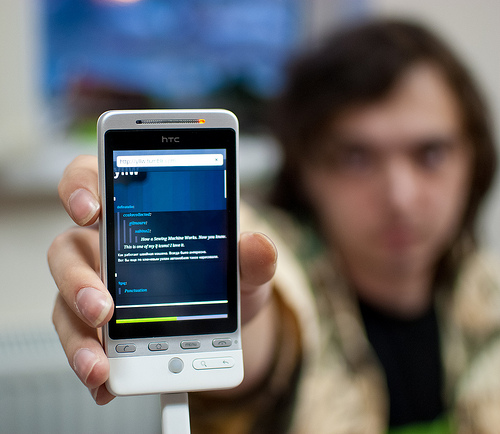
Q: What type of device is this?
A: Cell Phone.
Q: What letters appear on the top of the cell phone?
A: Htc.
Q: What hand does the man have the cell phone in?
A: Right.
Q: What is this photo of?
A: A man.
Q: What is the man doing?
A: Holding a phone.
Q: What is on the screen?
A: A program.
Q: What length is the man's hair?
A: Long.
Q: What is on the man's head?
A: His hair.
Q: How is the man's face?
A: Blurry.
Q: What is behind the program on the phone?
A: A blue screen.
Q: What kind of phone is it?
A: A htc.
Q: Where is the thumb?
A: On the phone.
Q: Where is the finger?
A: On the phone.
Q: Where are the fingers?
A: On the phone.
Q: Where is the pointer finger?
A: On the phone.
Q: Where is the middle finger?
A: On the phone.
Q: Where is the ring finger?
A: On the phone.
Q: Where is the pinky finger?
A: On the phone.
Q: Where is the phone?
A: In the hand.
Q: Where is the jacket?
A: On the man.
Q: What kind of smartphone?
A: HTC.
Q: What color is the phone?
A: White.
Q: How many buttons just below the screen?
A: Four.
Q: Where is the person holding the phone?
A: In their hand.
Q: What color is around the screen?
A: Black.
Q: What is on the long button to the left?
A: Magnifying glass.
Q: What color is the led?
A: Amber.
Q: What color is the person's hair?
A: Brown.